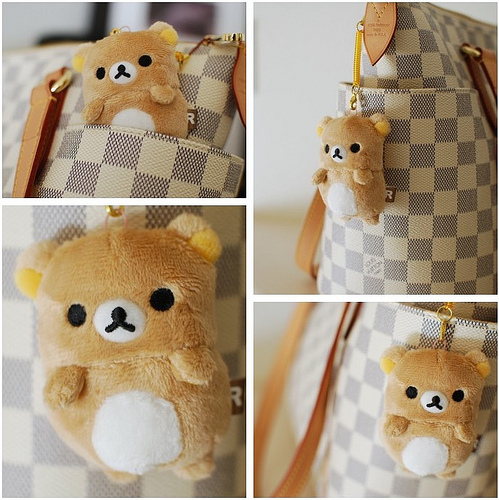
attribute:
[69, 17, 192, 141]
bear — brown, hanging, stuffed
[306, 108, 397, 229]
bear — brown, hanging, stuffed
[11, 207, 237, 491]
bear — brown, hanging, stuffed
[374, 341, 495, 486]
bear — brown, hanging, stuffed